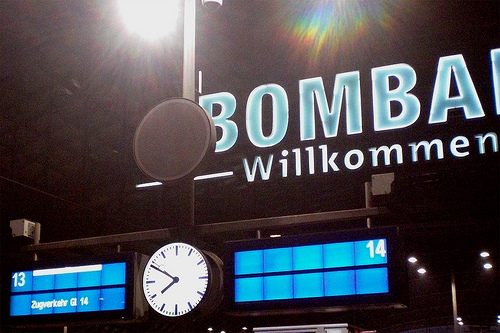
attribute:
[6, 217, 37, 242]
box — brown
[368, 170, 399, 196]
box — brown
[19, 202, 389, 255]
beam — metal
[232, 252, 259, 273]
square — blue, lit-up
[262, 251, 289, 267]
square — blue, lit-up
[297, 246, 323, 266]
square — blue, lit-up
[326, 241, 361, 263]
square — blue, lit-up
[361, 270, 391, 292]
square — blue, lit-up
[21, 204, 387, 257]
rod — metal, brown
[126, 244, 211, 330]
clock — bright face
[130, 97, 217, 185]
circle — dark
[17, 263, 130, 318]
screen — blue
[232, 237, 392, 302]
lights — blue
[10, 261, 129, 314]
lights — blue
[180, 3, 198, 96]
pole — gray 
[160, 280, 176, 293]
clock hand — short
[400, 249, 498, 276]
lights — in distance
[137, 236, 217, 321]
clock — white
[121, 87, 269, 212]
speaker — black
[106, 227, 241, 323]
clock — small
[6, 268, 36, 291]
13 — number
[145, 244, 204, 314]
numbers — black 